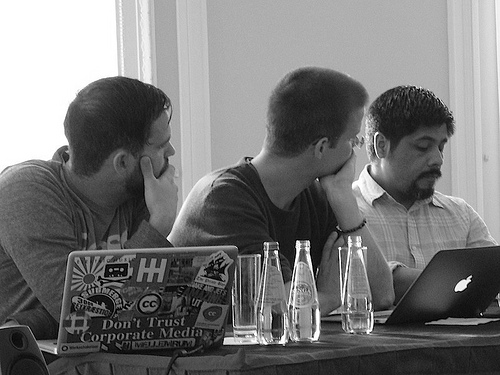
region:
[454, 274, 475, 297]
apple logo on laptop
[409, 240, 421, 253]
white button on shirt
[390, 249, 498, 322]
back of the laptop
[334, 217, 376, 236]
black bracelet on wrist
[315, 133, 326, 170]
the man's right ear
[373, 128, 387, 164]
the right ear of man on laptop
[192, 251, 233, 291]
sticker on laptop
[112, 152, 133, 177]
right ear of the man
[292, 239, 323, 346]
clear glass bottle on table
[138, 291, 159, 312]
sticker of cc on back of laptop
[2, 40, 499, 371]
three guys sitting at a table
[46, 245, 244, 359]
laptop is covered in stickers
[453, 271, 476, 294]
Apple logo on the back of the laptop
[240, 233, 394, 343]
three clear bottles on the table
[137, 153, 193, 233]
hand is resting on the mouth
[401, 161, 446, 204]
hair growing around the mouth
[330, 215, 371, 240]
thin band around the wrist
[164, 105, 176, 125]
strand of hair laying on the forehead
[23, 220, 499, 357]
two laptops on the table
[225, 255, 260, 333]
clear glass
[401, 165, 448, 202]
a man's black beard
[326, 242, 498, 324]
part of a laptop computer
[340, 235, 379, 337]
a tall glass bottle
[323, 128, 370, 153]
part of a man's eyeglasses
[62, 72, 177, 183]
a man's short cut hair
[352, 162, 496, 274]
part of a man's shirt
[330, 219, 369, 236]
part of a man's bracelet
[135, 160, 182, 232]
the hand of a man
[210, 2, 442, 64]
a white painted wall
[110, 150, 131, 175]
the ear of a man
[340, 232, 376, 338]
clear oblong glass bottle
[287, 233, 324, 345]
clear oblong glass bottle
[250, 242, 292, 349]
clear oblong glass bottle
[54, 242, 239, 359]
sticker covered lap top computer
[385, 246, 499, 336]
apple mac book computer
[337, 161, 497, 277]
collared plaid shirt with buttons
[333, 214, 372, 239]
bracelet on man's left arm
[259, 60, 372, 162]
short buzzed hair cut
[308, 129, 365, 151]
man's wire framed glasses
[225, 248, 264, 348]
tall clear water glass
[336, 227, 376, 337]
glass bottle on the table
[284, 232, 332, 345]
glass bottle on the table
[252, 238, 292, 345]
glass bottle on the table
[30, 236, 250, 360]
laptop on the table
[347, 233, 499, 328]
laptop on the table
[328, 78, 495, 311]
person with dark hair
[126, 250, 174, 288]
sticker on a laptop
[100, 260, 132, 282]
sticker on a laptop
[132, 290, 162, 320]
sticker on a laptop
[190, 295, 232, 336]
sticker on a laptop